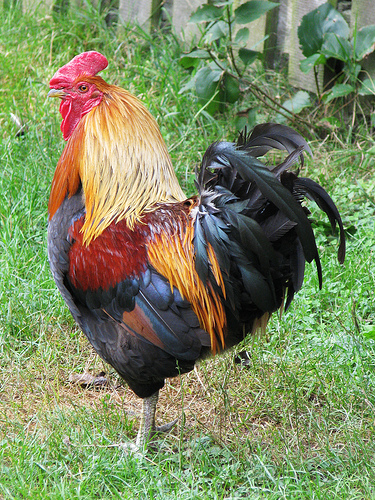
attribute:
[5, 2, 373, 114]
fence — wood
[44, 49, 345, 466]
rooster — standing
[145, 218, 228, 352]
feather — oragne , side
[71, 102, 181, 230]
feathers — yellow , orange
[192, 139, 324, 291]
feather — black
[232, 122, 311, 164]
feather — black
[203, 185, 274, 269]
feather — black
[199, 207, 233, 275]
feather — black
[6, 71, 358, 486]
grass — brown, green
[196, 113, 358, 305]
feathers — black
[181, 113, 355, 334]
tail — rooster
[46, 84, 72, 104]
beak — rooster 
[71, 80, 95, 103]
eye — open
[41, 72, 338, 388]
feathers — colorful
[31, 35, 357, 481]
rooster — yellow, black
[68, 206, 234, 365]
wings —  red, 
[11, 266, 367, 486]
grass — brown patch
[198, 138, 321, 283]
feather — bright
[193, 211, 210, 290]
feather — bright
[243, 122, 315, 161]
feather — bright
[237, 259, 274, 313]
feather — bright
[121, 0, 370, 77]
fence — wood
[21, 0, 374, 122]
fence — wooden, picket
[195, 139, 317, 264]
feather — dark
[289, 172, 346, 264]
feather — dark, black, bright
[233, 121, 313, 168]
feather — dark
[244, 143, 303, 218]
feather — dark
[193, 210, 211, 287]
feather — dark